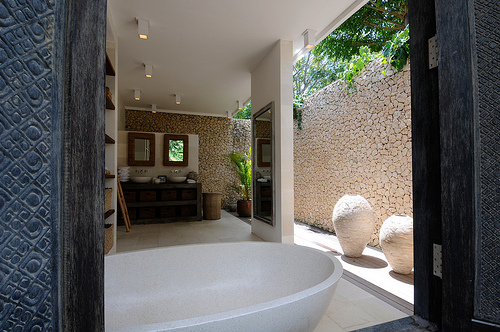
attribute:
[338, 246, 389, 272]
shadow — of statue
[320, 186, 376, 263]
pot — decorative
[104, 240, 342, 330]
bathtub — in front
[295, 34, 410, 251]
wall — stone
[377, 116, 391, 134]
stone — small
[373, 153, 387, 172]
stone — small